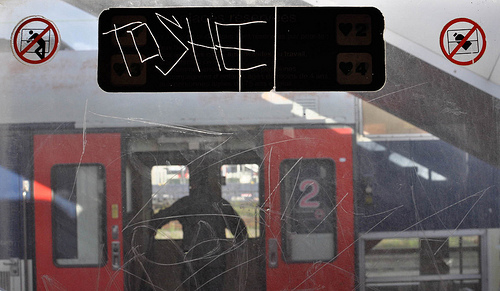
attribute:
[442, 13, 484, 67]
label — no bottles, no beverages, informative, red, no drinking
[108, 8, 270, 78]
graffiti — white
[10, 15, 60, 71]
label — no passenger, no leaning over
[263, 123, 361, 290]
door — open, red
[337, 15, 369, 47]
label — number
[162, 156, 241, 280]
person — standing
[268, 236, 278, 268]
handle — silver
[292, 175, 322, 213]
label — number, 2, red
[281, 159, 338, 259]
window — small